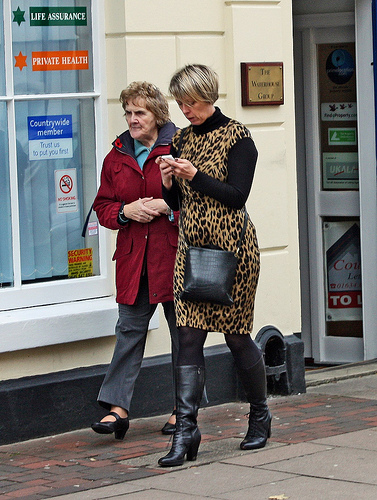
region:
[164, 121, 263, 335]
animal print dress on woman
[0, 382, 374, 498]
mixed brick walkway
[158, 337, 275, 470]
black, high-heeled boots on woman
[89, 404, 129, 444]
high-heeled Mary Jane Shoes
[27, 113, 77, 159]
Window sticker advertisement for "Countrywide"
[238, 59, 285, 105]
brass and wood wall plack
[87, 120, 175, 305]
red and blue winter coat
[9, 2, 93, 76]
green-and-white and red-and-white window stickers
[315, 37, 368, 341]
business banners in window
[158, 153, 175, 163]
cell phone in woman's hand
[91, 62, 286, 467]
two women are walking on a sidewalk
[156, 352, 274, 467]
the black leather boots have heels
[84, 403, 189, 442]
the shoes are black with heels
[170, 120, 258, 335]
the girl has an animal print jumper on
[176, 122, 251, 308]
the person has a black purse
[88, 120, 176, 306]
the lady has a maroon coat on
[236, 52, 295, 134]
a plaque is on the building's wall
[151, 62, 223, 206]
the lady is on the cell phone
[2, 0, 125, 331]
a window is in the building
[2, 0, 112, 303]
the window has white trim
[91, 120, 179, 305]
red jacket on the lady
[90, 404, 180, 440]
black heels on the woman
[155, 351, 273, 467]
black boots on the woman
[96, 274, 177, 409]
dark gray pants on the woman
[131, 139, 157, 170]
woman wearing a blue shirt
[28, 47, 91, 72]
red and white sign in the window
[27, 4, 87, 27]
green and white sign in the window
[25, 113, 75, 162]
blue and white sign in the window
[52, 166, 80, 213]
white sign with red and black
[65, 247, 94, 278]
red, black and yellow sign in the window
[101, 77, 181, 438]
that is a lady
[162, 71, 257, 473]
that is a lady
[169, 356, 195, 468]
that is a boot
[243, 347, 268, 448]
that is a boot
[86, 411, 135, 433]
that is a shoe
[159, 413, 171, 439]
that is a shoe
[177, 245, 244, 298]
that is a handbag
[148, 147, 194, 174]
she is using her phone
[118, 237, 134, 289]
that is a red jacket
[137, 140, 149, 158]
that is a blue shirt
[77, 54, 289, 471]
Two women are walking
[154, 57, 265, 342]
Woman is wearing a leopard print dress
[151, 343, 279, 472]
Woman is wearing leather boots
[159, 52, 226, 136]
Woman has blonde hair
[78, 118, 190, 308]
Woman is wearing a dark red coat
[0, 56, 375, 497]
Women are walking on the sidewalk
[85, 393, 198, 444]
Woman is wearing black shoes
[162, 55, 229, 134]
Woman is looking down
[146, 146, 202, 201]
Woman is holding an electronic device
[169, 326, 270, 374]
Woman is wearing black stockings